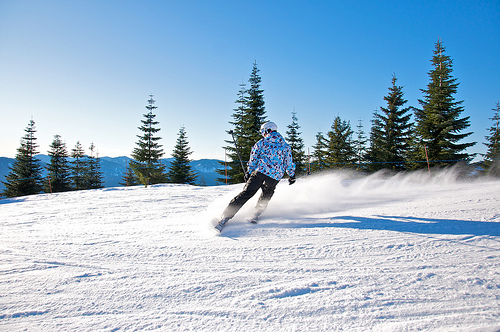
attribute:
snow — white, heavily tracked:
[1, 177, 499, 331]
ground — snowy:
[1, 179, 497, 332]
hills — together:
[0, 146, 242, 194]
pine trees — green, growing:
[0, 33, 499, 197]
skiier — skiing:
[210, 118, 299, 238]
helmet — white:
[256, 120, 279, 139]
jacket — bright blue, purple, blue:
[240, 132, 298, 183]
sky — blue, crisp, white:
[2, 1, 500, 161]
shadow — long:
[263, 210, 499, 245]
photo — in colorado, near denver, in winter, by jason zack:
[0, 0, 499, 330]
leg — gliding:
[211, 167, 264, 230]